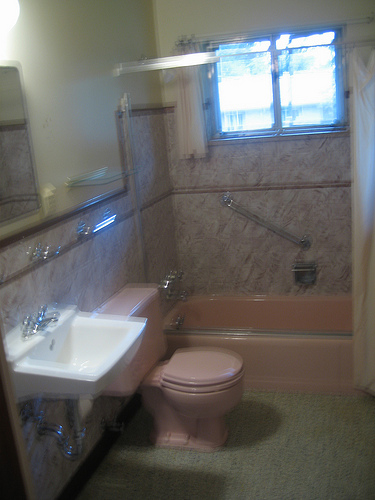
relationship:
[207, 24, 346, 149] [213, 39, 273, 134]
window composed of a glass panel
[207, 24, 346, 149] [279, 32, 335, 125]
window composed of a glass panel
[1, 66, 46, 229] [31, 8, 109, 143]
mirror hanging on wall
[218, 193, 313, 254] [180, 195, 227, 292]
handle bar affixed to wall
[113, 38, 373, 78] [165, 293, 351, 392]
curtain holder above bathtub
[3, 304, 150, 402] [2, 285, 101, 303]
sink mounted on wall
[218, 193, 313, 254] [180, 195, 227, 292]
grab bar mounted on wall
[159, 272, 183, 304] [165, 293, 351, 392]
faucet above tub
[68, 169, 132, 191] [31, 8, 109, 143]
glass shelf mounted on wall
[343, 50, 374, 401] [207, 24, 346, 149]
curtain hanging near a window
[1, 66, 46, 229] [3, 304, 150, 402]
mirror mounted above sink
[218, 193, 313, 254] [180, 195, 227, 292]
handicap bar attached to wall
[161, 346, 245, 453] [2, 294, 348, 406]
ceramic toilet between sink and tub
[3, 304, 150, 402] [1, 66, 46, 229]
sink under mirror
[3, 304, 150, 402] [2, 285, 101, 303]
sink attached to wall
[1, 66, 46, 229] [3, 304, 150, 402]
mirror above sink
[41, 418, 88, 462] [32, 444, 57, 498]
pipe from wall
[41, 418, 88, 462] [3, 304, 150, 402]
pipe to sink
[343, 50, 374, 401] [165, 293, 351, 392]
shower curtain in front of tub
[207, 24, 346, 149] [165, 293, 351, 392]
window above tub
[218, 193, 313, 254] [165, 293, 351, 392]
silver handle in a bath tub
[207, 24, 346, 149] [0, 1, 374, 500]
rectangle window inside bathroom